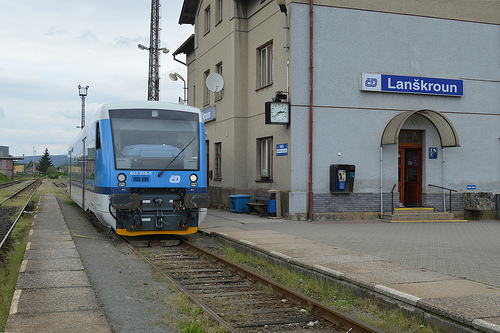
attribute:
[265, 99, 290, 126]
clock — square, face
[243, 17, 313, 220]
wall — building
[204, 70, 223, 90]
satellite dish — white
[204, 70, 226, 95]
satellite dish — white, large, round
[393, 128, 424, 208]
door — dark , red colored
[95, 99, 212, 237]
train front — blue, white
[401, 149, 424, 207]
door — red 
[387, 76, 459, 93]
writing — white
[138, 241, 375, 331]
track — railroad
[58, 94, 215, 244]
train — blue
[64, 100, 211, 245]
train — dark green, yellow, lower part, blue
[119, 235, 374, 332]
track — railroad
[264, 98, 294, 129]
clock — black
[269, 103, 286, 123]
face — white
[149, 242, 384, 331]
tracks — rusted, metal, train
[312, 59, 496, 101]
sign — blue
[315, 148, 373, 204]
metal protector — dark, hood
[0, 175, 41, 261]
track — railroad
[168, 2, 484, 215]
building — side